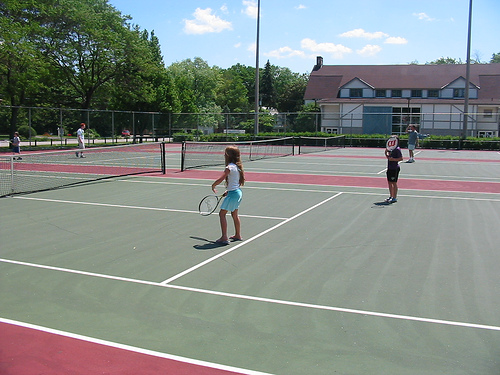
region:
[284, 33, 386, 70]
the clouds are white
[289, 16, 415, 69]
the sky is blue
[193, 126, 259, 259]
the girl is standing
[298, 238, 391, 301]
the turf is green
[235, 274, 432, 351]
the line is white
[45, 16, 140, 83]
the leaves are green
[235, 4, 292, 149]
the pole is tall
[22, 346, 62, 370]
the turf is red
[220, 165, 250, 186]
the shirt is white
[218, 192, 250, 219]
the pants are blue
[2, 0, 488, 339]
There are clouds in the sky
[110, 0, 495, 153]
The sky is blue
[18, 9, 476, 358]
The photo was taken on a tennis court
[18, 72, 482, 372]
The people are playing tennis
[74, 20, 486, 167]
There is a building in the background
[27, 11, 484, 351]
The photo was taken during the day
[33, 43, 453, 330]
The photo was taken outside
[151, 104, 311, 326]
A young girl is holding a racquet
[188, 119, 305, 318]
The young girl is wearing a white shirt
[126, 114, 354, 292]
The young girl has long hair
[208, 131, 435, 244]
young people playing tennis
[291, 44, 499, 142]
building with red roof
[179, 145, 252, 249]
young girl holding tennis racket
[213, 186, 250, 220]
girl wearing blue shorts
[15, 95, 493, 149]
chain link fence around court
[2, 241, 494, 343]
lines painted on tennis court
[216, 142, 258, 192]
girl with long blonde hair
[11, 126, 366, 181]
three tennis nets on court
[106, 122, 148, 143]
car on street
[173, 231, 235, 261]
shadow of girl on tennis court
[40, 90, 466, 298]
People on a tennis court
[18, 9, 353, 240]
Trees are in the background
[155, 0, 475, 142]
Clouds in the sky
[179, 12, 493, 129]
Sky is blue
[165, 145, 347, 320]
Young girl with a racquet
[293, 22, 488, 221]
Building in the background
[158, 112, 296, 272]
The girl is wearing shorts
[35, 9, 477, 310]
Photo was taken on a sunny day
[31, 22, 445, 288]
Fence around the tennis court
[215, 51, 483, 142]
large clubhouse painted brown and white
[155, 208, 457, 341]
three large green tennis courts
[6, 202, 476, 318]
boundary lines painted on tennis courts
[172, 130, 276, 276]
young girl dressed in blue shorts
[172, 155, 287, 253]
young girl with long blond hair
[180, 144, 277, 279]
young girl with tennis racquet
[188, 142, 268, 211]
young girl with white pullover shirt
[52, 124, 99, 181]
tennis player dressed in white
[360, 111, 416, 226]
tennis player dressed in black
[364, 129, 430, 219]
tennis player holding a Wilson racquet